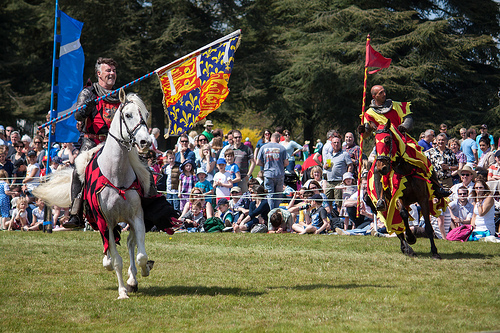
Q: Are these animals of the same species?
A: Yes, all the animals are horses.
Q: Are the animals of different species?
A: No, all the animals are horses.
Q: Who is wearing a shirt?
A: The man is wearing a shirt.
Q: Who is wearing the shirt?
A: The man is wearing a shirt.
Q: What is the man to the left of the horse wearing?
A: The man is wearing a shirt.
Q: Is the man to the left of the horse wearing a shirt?
A: Yes, the man is wearing a shirt.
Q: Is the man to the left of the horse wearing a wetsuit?
A: No, the man is wearing a shirt.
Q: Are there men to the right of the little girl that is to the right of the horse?
A: Yes, there is a man to the right of the girl.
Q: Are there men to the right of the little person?
A: Yes, there is a man to the right of the girl.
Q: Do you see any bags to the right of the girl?
A: No, there is a man to the right of the girl.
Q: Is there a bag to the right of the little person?
A: No, there is a man to the right of the girl.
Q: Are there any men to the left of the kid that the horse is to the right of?
A: Yes, there is a man to the left of the kid.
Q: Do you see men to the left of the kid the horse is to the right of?
A: Yes, there is a man to the left of the kid.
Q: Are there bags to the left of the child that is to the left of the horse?
A: No, there is a man to the left of the child.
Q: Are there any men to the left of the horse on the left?
A: No, the man is to the right of the horse.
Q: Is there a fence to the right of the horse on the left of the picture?
A: No, there is a man to the right of the horse.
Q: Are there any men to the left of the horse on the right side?
A: Yes, there is a man to the left of the horse.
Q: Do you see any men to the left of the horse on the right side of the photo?
A: Yes, there is a man to the left of the horse.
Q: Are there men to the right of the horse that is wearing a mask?
A: No, the man is to the left of the horse.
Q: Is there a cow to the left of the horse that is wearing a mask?
A: No, there is a man to the left of the horse.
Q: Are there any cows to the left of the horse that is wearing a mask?
A: No, there is a man to the left of the horse.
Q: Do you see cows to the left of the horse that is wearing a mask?
A: No, there is a man to the left of the horse.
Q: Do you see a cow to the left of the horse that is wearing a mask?
A: No, there is a man to the left of the horse.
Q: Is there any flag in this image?
A: Yes, there is a flag.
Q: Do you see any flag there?
A: Yes, there is a flag.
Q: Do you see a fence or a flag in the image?
A: Yes, there is a flag.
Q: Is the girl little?
A: Yes, the girl is little.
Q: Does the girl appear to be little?
A: Yes, the girl is little.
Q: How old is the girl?
A: The girl is little.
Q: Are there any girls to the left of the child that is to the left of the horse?
A: Yes, there is a girl to the left of the kid.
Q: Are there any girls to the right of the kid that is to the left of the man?
A: No, the girl is to the left of the child.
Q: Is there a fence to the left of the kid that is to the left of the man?
A: No, there is a girl to the left of the child.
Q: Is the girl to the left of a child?
A: Yes, the girl is to the left of a child.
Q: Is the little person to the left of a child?
A: Yes, the girl is to the left of a child.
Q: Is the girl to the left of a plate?
A: No, the girl is to the left of a child.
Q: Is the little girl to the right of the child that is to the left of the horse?
A: No, the girl is to the left of the child.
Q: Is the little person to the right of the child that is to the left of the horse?
A: No, the girl is to the left of the child.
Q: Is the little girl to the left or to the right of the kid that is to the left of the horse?
A: The girl is to the left of the child.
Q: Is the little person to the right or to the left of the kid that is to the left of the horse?
A: The girl is to the left of the child.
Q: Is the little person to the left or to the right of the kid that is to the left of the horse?
A: The girl is to the left of the child.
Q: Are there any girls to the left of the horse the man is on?
A: No, the girl is to the right of the horse.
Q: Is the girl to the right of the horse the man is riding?
A: Yes, the girl is to the right of the horse.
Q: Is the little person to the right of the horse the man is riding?
A: Yes, the girl is to the right of the horse.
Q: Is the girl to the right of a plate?
A: No, the girl is to the right of the horse.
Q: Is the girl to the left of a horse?
A: No, the girl is to the right of a horse.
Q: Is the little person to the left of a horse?
A: No, the girl is to the right of a horse.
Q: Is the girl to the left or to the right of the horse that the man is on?
A: The girl is to the right of the horse.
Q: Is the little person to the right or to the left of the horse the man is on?
A: The girl is to the right of the horse.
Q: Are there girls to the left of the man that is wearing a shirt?
A: Yes, there is a girl to the left of the man.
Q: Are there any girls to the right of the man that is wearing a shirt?
A: No, the girl is to the left of the man.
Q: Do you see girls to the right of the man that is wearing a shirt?
A: No, the girl is to the left of the man.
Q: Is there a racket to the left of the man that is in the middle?
A: No, there is a girl to the left of the man.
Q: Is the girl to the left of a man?
A: Yes, the girl is to the left of a man.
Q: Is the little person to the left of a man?
A: Yes, the girl is to the left of a man.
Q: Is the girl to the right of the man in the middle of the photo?
A: No, the girl is to the left of the man.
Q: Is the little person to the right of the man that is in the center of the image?
A: No, the girl is to the left of the man.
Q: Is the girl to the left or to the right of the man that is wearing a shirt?
A: The girl is to the left of the man.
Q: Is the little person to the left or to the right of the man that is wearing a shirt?
A: The girl is to the left of the man.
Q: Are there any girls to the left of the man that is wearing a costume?
A: Yes, there is a girl to the left of the man.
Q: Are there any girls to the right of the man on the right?
A: No, the girl is to the left of the man.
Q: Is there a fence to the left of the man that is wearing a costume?
A: No, there is a girl to the left of the man.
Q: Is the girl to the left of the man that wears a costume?
A: Yes, the girl is to the left of the man.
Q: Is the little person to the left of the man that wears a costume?
A: Yes, the girl is to the left of the man.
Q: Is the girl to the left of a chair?
A: No, the girl is to the left of the man.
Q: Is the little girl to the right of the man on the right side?
A: No, the girl is to the left of the man.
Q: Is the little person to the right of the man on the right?
A: No, the girl is to the left of the man.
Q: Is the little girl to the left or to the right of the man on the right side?
A: The girl is to the left of the man.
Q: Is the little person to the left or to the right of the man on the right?
A: The girl is to the left of the man.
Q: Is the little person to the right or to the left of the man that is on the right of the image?
A: The girl is to the left of the man.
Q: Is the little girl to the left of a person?
A: Yes, the girl is to the left of a person.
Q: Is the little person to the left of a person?
A: Yes, the girl is to the left of a person.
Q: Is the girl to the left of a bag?
A: No, the girl is to the left of a person.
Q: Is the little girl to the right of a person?
A: No, the girl is to the left of a person.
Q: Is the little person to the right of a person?
A: No, the girl is to the left of a person.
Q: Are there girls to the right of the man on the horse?
A: Yes, there is a girl to the right of the man.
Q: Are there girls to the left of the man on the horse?
A: No, the girl is to the right of the man.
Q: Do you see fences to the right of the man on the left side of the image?
A: No, there is a girl to the right of the man.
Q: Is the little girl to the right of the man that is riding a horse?
A: Yes, the girl is to the right of the man.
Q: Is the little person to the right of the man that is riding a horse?
A: Yes, the girl is to the right of the man.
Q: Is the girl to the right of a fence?
A: No, the girl is to the right of the man.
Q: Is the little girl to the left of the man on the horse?
A: No, the girl is to the right of the man.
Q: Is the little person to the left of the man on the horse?
A: No, the girl is to the right of the man.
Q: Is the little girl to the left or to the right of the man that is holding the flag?
A: The girl is to the right of the man.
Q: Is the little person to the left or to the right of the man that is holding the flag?
A: The girl is to the right of the man.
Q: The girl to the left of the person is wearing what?
A: The girl is wearing a hat.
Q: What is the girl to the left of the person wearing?
A: The girl is wearing a hat.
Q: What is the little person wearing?
A: The girl is wearing a hat.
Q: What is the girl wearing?
A: The girl is wearing a hat.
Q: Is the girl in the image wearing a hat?
A: Yes, the girl is wearing a hat.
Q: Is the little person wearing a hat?
A: Yes, the girl is wearing a hat.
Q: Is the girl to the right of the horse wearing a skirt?
A: No, the girl is wearing a hat.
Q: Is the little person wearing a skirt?
A: No, the girl is wearing a hat.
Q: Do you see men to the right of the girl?
A: Yes, there is a man to the right of the girl.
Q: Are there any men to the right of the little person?
A: Yes, there is a man to the right of the girl.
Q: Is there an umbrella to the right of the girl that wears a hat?
A: No, there is a man to the right of the girl.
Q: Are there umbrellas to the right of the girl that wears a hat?
A: No, there is a man to the right of the girl.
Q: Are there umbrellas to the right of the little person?
A: No, there is a man to the right of the girl.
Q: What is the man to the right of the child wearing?
A: The man is wearing a costume.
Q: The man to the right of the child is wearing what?
A: The man is wearing a costume.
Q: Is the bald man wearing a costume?
A: Yes, the man is wearing a costume.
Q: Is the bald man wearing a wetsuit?
A: No, the man is wearing a costume.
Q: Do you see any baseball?
A: No, there are no baseballs.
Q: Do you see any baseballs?
A: No, there are no baseballs.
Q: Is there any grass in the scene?
A: Yes, there is grass.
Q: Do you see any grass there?
A: Yes, there is grass.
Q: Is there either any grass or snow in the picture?
A: Yes, there is grass.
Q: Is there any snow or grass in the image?
A: Yes, there is grass.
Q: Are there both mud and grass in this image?
A: No, there is grass but no mud.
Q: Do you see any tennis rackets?
A: No, there are no tennis rackets.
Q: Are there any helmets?
A: No, there are no helmets.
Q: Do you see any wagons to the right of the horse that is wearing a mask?
A: No, there is a person to the right of the horse.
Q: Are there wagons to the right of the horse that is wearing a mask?
A: No, there is a person to the right of the horse.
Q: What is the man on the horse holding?
A: The man is holding the flag.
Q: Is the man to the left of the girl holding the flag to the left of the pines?
A: Yes, the man is holding the flag.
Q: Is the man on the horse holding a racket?
A: No, the man is holding the flag.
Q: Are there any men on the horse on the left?
A: Yes, there is a man on the horse.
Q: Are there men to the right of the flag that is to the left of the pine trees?
A: No, the man is to the left of the flag.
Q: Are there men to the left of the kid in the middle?
A: Yes, there is a man to the left of the child.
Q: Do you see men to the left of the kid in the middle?
A: Yes, there is a man to the left of the child.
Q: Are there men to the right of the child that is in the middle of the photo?
A: No, the man is to the left of the child.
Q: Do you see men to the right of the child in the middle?
A: No, the man is to the left of the child.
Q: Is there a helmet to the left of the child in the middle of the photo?
A: No, there is a man to the left of the kid.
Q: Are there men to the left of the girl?
A: Yes, there is a man to the left of the girl.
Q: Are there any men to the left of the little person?
A: Yes, there is a man to the left of the girl.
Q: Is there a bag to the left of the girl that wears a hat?
A: No, there is a man to the left of the girl.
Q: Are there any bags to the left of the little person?
A: No, there is a man to the left of the girl.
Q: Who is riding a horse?
A: The man is riding a horse.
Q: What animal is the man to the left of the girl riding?
A: The man is riding a horse.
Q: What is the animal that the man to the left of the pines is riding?
A: The animal is a horse.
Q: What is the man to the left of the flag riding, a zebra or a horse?
A: The man is riding a horse.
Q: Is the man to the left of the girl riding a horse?
A: Yes, the man is riding a horse.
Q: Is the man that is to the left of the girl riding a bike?
A: No, the man is riding a horse.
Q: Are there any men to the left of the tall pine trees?
A: Yes, there is a man to the left of the pines.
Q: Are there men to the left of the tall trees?
A: Yes, there is a man to the left of the pines.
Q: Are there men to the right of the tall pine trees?
A: No, the man is to the left of the pine trees.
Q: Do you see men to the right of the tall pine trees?
A: No, the man is to the left of the pine trees.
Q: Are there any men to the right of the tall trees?
A: No, the man is to the left of the pine trees.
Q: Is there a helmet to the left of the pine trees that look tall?
A: No, there is a man to the left of the pines.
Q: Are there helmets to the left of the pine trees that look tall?
A: No, there is a man to the left of the pines.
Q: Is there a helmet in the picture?
A: No, there are no helmets.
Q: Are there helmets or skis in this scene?
A: No, there are no helmets or skis.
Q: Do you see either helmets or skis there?
A: No, there are no helmets or skis.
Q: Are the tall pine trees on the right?
A: Yes, the pines are on the right of the image.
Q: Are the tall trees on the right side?
A: Yes, the pines are on the right of the image.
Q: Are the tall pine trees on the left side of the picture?
A: No, the pine trees are on the right of the image.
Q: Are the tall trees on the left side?
A: No, the pine trees are on the right of the image.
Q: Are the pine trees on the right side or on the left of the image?
A: The pine trees are on the right of the image.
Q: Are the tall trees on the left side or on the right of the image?
A: The pine trees are on the right of the image.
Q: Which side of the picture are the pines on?
A: The pines are on the right of the image.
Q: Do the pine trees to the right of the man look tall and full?
A: Yes, the pines are tall and full.